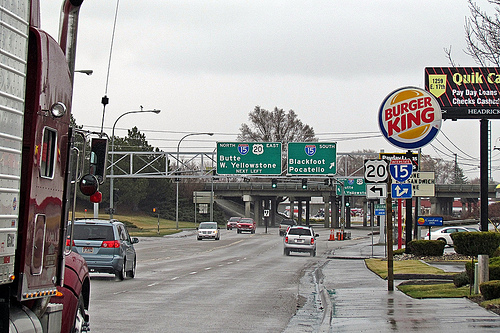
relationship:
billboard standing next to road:
[423, 65, 483, 121] [87, 222, 377, 332]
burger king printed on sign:
[380, 95, 435, 137] [378, 86, 443, 150]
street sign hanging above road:
[214, 140, 282, 177] [87, 225, 377, 331]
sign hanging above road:
[286, 140, 338, 175] [87, 225, 377, 331]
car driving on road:
[63, 213, 138, 281] [87, 225, 377, 331]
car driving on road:
[194, 220, 222, 240] [87, 225, 377, 331]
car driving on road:
[280, 221, 319, 256] [87, 225, 377, 331]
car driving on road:
[233, 216, 256, 232] [87, 225, 377, 331]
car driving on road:
[224, 213, 244, 230] [87, 225, 377, 331]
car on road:
[63, 213, 138, 281] [119, 240, 273, 327]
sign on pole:
[373, 83, 444, 152] [403, 152, 413, 250]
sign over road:
[212, 133, 285, 183] [87, 225, 377, 331]